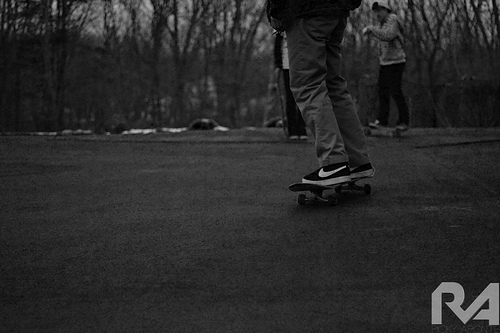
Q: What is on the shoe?
A: A white logo.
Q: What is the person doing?
A: Riding a skateboard.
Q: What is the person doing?
A: Riding a skateboard.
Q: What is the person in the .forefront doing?
A: Riding a skateboard.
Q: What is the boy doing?
A: Riding a skateboard.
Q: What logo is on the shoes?
A: Nike swoosh.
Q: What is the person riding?
A: Skateboard.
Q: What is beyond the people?
A: Trees.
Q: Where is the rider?
A: On the skateboard.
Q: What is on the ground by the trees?
A: Snow.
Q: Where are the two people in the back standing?
A: By the curb.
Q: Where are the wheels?
A: Under the skateboard.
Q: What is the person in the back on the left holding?
A: Skateboard.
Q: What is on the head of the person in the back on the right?
A: Hat.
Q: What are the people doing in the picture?
A: Skateboarding.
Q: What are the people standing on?
A: Skateboards.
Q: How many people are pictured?
A: Three.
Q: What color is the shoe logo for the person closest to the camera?
A: White.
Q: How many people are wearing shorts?
A: None.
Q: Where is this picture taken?
A: On the sidewalk.